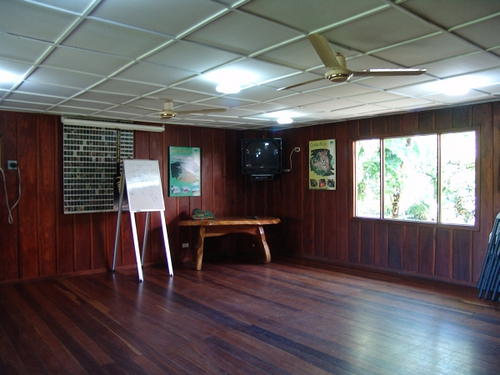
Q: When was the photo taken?
A: Daytime.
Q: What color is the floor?
A: Brown.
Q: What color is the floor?
A: Brown.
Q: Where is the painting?
A: On the wall.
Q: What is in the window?
A: Trees.